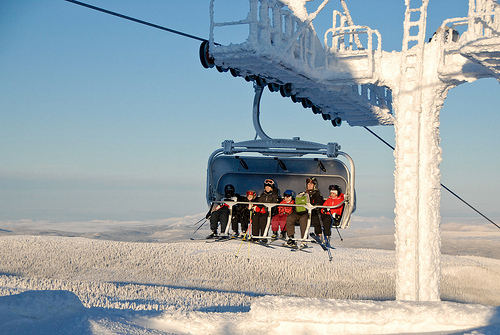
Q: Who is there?
A: Visitors.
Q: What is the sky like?
A: Clear.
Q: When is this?
A: Late afternoon.